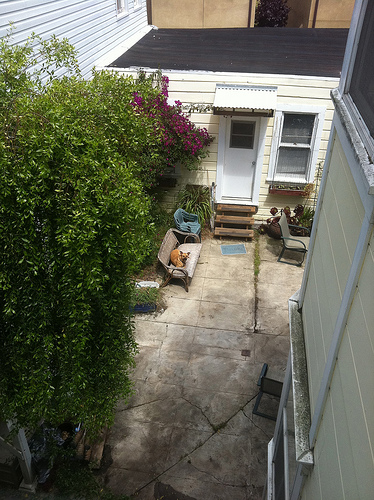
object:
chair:
[276, 211, 311, 266]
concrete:
[73, 234, 308, 500]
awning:
[211, 81, 279, 112]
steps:
[213, 226, 255, 238]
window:
[277, 110, 318, 152]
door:
[219, 243, 247, 256]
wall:
[285, 112, 374, 499]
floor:
[0, 234, 316, 499]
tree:
[0, 18, 217, 499]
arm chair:
[184, 232, 203, 244]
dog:
[168, 248, 190, 269]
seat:
[154, 226, 204, 293]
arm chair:
[280, 234, 306, 255]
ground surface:
[0, 223, 315, 499]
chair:
[251, 361, 284, 424]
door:
[214, 114, 266, 207]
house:
[92, 29, 353, 230]